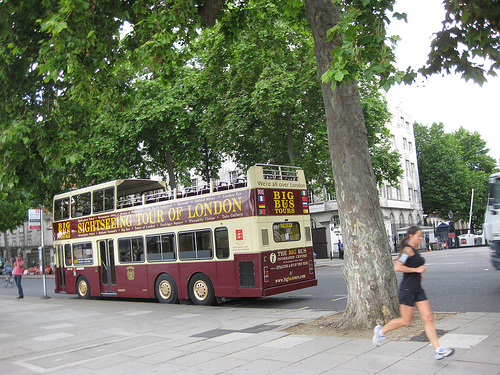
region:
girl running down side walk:
[371, 222, 468, 372]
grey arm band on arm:
[397, 255, 407, 268]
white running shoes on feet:
[430, 349, 456, 360]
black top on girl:
[388, 250, 432, 284]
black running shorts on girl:
[394, 286, 434, 308]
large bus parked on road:
[53, 157, 303, 297]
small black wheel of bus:
[151, 255, 179, 305]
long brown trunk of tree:
[312, 72, 395, 320]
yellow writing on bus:
[160, 197, 241, 222]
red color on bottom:
[97, 265, 254, 287]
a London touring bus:
[34, 156, 324, 319]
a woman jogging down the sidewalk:
[361, 215, 461, 364]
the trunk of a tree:
[323, 199, 400, 316]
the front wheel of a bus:
[71, 272, 94, 298]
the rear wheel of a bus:
[146, 270, 179, 305]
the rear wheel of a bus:
[181, 271, 218, 306]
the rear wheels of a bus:
[149, 268, 212, 309]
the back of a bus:
[247, 154, 321, 298]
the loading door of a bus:
[96, 235, 119, 295]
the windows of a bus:
[117, 233, 233, 261]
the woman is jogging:
[369, 200, 471, 374]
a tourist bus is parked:
[20, 151, 322, 338]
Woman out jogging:
[371, 224, 454, 361]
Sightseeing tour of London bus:
[51, 162, 318, 306]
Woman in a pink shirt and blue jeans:
[9, 251, 26, 300]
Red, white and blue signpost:
[27, 205, 47, 297]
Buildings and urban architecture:
[0, 98, 423, 272]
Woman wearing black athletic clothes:
[370, 225, 455, 360]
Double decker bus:
[51, 162, 320, 307]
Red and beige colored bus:
[52, 163, 318, 322]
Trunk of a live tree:
[300, 0, 405, 332]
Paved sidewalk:
[0, 292, 498, 374]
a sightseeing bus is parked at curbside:
[49, 161, 320, 302]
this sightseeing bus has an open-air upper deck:
[112, 158, 305, 208]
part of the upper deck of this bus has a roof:
[52, 175, 164, 245]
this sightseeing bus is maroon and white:
[50, 160, 317, 307]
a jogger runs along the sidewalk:
[367, 218, 456, 361]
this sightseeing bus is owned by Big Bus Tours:
[266, 185, 300, 218]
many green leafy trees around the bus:
[2, 0, 403, 185]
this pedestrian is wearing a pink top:
[8, 250, 28, 302]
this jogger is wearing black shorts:
[393, 273, 430, 309]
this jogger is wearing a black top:
[396, 241, 428, 274]